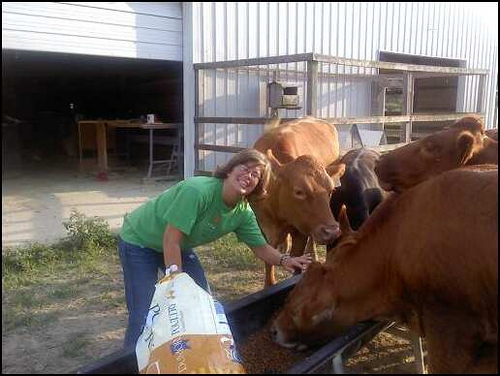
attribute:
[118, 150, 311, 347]
lady — smiling, reaching, petting, feeding, bending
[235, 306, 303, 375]
feed — brown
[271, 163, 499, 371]
cow — eating, brown, black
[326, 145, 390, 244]
cow — black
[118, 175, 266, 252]
shirt — green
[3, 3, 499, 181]
building — white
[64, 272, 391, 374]
feed bin — black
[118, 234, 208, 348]
pants — blue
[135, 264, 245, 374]
bag — brow, white, filled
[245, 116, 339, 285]
cow — brown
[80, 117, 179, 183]
table — inside a barn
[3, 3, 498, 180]
barn — white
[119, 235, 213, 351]
jeans — blue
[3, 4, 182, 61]
door — metal